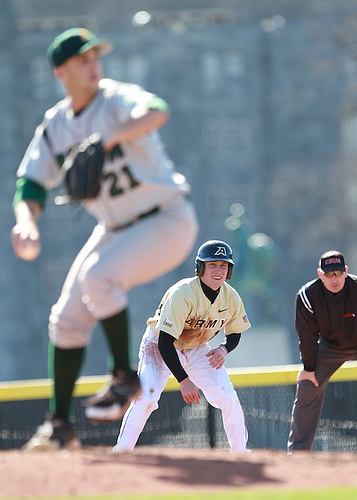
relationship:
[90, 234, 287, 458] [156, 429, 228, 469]
runner on base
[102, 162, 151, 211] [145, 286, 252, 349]
number on shirt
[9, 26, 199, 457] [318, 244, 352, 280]
man has hat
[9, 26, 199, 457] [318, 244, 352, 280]
man wearing hat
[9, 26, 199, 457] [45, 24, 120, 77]
man has helmet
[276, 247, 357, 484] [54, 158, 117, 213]
umpire has mit